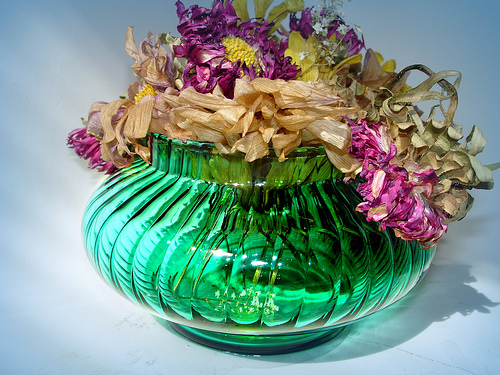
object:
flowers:
[53, 2, 500, 205]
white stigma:
[297, 47, 311, 66]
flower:
[349, 158, 451, 249]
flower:
[118, 16, 182, 92]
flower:
[356, 41, 413, 102]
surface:
[2, 126, 497, 371]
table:
[0, 188, 79, 364]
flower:
[59, 96, 142, 181]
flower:
[176, 2, 291, 92]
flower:
[125, 30, 190, 120]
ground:
[426, 109, 452, 135]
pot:
[59, 109, 498, 355]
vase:
[61, 125, 438, 372]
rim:
[145, 127, 327, 155]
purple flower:
[348, 130, 445, 253]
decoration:
[59, 3, 489, 277]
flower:
[285, 32, 360, 84]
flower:
[218, 33, 258, 65]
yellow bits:
[223, 34, 261, 73]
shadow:
[391, 242, 484, 352]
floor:
[0, 1, 475, 375]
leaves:
[79, 22, 499, 223]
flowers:
[65, 1, 499, 249]